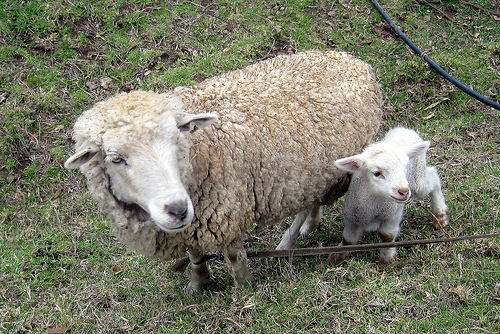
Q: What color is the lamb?
A: White.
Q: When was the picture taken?
A: During the day.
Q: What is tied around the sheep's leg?
A: A thick string.